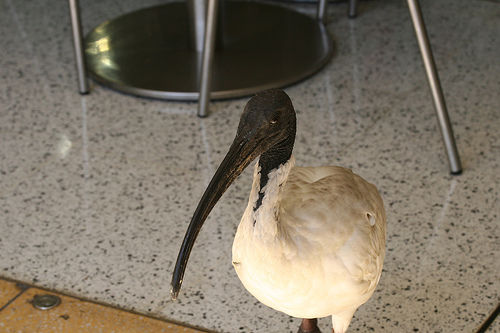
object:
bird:
[168, 87, 387, 332]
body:
[230, 165, 386, 318]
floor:
[0, 0, 499, 331]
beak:
[167, 140, 275, 299]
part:
[460, 101, 487, 143]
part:
[382, 91, 417, 190]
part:
[409, 210, 440, 282]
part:
[414, 268, 473, 320]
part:
[390, 238, 493, 271]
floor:
[0, 120, 168, 235]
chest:
[231, 236, 334, 318]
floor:
[81, 105, 149, 263]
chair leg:
[407, 0, 463, 174]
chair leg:
[196, 0, 218, 117]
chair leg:
[66, 0, 89, 95]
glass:
[66, 179, 146, 324]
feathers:
[303, 202, 377, 263]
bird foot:
[297, 320, 325, 332]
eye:
[269, 112, 281, 123]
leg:
[297, 316, 323, 332]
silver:
[86, 12, 147, 62]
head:
[230, 87, 298, 172]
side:
[249, 97, 297, 146]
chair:
[54, 0, 464, 175]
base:
[78, 2, 335, 101]